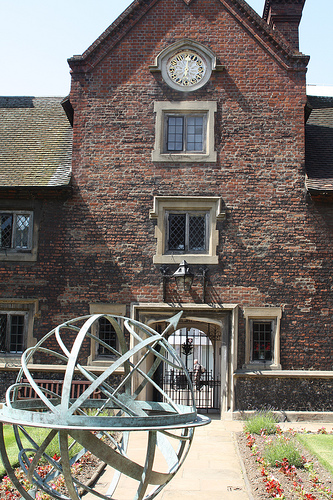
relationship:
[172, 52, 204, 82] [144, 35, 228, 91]
clock has frame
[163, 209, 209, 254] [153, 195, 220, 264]
mesh on window